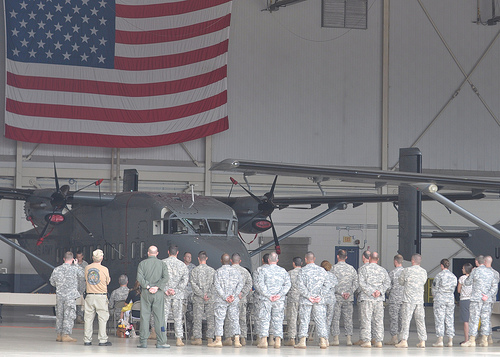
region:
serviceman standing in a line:
[48, 243, 85, 335]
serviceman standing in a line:
[161, 250, 196, 337]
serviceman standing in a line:
[211, 251, 242, 349]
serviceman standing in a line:
[258, 252, 290, 344]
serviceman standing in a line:
[333, 240, 364, 333]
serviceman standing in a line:
[286, 251, 336, 348]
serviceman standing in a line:
[353, 250, 384, 345]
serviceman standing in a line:
[400, 248, 436, 344]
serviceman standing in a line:
[426, 221, 458, 347]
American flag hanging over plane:
[2, 0, 231, 144]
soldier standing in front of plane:
[214, 251, 242, 342]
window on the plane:
[161, 220, 234, 235]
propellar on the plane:
[21, 161, 98, 243]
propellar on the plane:
[231, 172, 293, 249]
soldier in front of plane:
[401, 253, 427, 348]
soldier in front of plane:
[192, 244, 212, 341]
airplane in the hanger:
[6, 146, 483, 253]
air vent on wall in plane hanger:
[321, 2, 371, 27]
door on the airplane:
[133, 218, 148, 263]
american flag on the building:
[4, 1, 239, 152]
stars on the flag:
[5, 5, 108, 55]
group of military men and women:
[42, 237, 495, 352]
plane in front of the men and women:
[26, 176, 262, 246]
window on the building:
[312, 5, 379, 45]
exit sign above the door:
[340, 232, 356, 247]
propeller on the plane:
[30, 165, 104, 240]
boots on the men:
[217, 334, 244, 347]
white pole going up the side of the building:
[377, 20, 392, 167]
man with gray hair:
[265, 251, 280, 264]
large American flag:
[1, 4, 231, 143]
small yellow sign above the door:
[341, 235, 351, 240]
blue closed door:
[336, 246, 358, 267]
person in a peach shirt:
[83, 248, 110, 345]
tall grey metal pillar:
[396, 145, 421, 259]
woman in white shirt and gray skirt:
[456, 262, 473, 344]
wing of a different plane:
[210, 157, 497, 237]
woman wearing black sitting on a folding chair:
[125, 279, 140, 316]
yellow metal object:
[426, 277, 433, 302]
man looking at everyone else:
[182, 250, 195, 334]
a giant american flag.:
[0, 0, 240, 162]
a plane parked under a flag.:
[0, 147, 490, 303]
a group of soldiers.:
[33, 247, 496, 351]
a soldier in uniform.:
[135, 234, 173, 341]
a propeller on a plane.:
[216, 172, 324, 254]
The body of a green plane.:
[11, 186, 257, 308]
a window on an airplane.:
[140, 194, 247, 251]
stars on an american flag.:
[0, 0, 115, 66]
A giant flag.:
[0, 6, 240, 151]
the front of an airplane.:
[143, 199, 269, 291]